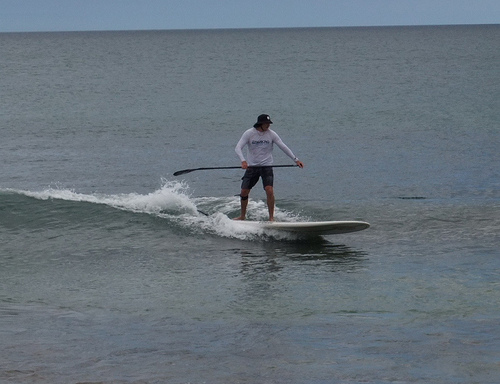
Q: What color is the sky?
A: Blue.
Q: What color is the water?
A: Gray.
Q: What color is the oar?
A: Black.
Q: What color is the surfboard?
A: White.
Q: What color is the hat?
A: Black.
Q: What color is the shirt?
A: White.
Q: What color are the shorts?
A: Black.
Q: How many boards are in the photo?
A: One.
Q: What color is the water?
A: Blue.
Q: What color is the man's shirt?
A: White.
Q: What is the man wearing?
A: Black shorts.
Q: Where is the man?
A: In the middle of the water.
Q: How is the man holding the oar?
A: It is being carried.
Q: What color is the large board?
A: White.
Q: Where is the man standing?
A: On the white board.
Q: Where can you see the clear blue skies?
A: In the top of the picture.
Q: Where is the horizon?
A: Behind the man.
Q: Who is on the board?
A: A surfer holding a paddle.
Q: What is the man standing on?
A: A surfboard.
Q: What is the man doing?
A: Surfing.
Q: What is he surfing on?
A: Surfboard.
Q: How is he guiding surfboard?
A: Oar.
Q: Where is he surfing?
A: Water.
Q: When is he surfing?
A: Evening.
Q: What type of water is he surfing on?
A: Calm.